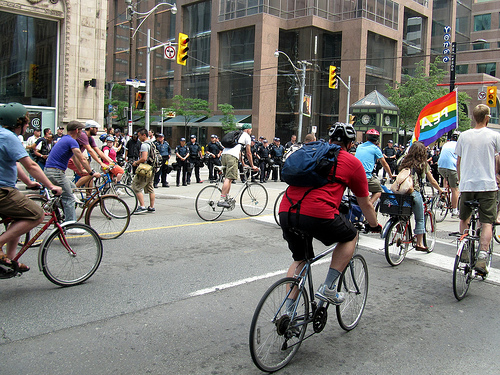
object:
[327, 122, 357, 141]
helmet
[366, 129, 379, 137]
helmet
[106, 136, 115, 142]
helmet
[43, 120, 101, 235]
man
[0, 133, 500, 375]
road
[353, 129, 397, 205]
person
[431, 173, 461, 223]
bike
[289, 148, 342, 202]
man's back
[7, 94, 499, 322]
group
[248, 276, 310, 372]
wheel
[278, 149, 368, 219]
shirt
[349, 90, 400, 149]
tower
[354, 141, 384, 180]
shirt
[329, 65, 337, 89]
stop light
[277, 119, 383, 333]
person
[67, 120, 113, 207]
person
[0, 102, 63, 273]
person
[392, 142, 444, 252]
person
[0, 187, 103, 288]
bike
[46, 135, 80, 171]
shirt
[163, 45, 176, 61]
sign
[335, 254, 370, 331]
wheel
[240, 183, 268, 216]
wheel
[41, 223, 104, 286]
wheel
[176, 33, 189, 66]
traffic light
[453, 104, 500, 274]
man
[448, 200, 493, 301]
bicycle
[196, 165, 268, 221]
bicycle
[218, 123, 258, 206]
man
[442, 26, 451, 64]
sign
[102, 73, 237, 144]
trees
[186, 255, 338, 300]
paint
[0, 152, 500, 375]
ground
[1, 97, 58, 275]
person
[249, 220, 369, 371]
bike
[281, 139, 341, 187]
pack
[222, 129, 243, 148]
pack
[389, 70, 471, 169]
tree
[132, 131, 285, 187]
police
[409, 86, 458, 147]
flag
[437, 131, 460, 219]
bike rider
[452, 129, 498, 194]
white shirt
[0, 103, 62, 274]
people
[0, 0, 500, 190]
building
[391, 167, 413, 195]
pack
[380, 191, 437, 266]
bike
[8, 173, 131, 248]
bike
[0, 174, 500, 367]
street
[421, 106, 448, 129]
text